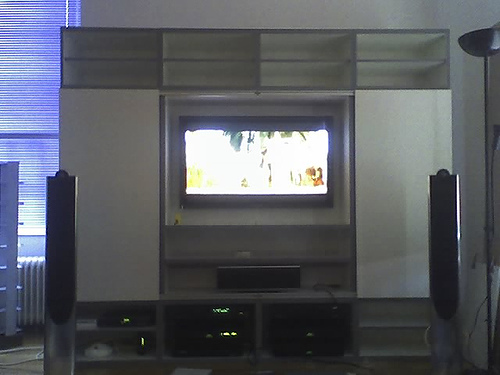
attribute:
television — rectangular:
[177, 117, 334, 206]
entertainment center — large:
[47, 24, 464, 374]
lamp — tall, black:
[455, 21, 499, 371]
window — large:
[4, 4, 76, 252]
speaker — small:
[211, 259, 311, 294]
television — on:
[170, 107, 341, 213]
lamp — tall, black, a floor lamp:
[447, 31, 498, 371]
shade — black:
[439, 20, 499, 71]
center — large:
[44, 15, 466, 356]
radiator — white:
[15, 256, 46, 328]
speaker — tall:
[421, 169, 471, 329]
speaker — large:
[40, 165, 85, 373]